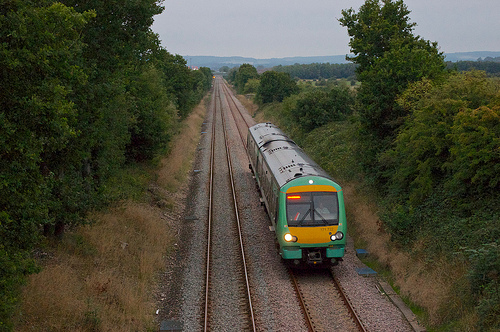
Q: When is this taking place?
A: Daytime.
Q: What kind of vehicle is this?
A: Train.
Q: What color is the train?
A: Green and yellow.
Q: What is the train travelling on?
A: Train tracks.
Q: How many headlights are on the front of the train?
A: Two.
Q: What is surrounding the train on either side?
A: Grass and trees.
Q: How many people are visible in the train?
A: One.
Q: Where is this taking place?
A: On the train tracks in the country.